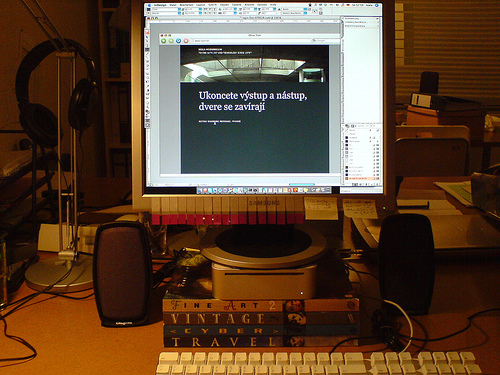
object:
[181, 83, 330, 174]
display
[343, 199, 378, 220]
note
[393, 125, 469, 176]
folder organizer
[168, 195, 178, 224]
tabs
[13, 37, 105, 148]
headphones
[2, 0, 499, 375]
desk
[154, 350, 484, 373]
keyboard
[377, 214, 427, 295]
speakers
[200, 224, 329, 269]
base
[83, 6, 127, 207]
bookcase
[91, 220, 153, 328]
speaker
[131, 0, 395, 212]
monitor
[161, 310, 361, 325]
books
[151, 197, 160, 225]
paper tab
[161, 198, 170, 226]
paper tab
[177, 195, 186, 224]
paper tab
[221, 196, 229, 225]
paper tab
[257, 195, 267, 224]
paper tab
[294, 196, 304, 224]
paper tabs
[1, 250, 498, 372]
table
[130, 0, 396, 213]
screen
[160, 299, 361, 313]
books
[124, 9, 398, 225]
monitor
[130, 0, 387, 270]
computer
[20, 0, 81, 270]
arm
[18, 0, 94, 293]
lamp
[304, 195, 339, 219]
note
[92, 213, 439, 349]
items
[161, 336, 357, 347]
books